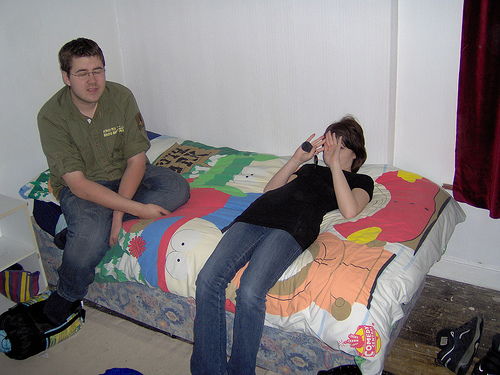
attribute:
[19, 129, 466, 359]
comforter — south park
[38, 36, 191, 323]
man — blinking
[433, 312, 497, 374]
shoes — black, gray, high top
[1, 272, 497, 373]
floor — hardwood, wor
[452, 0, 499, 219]
curtain — red, dark red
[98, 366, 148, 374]
shirt — blue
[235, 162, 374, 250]
shirt — black, short sleeved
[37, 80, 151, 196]
shirt — green, button down, olive gree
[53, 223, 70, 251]
sock — black, dark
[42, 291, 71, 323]
sock — black, dark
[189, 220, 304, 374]
jeans — blue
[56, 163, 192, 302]
jeans — blue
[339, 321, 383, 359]
logo — comedy central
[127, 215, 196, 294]
hat — blue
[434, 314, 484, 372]
shoe — black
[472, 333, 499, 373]
shoe — black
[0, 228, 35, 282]
shelf — white